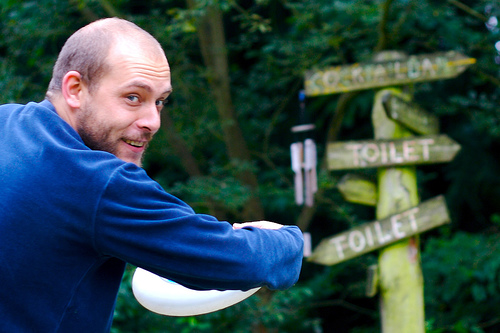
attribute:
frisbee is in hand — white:
[130, 226, 266, 316]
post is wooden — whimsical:
[369, 46, 429, 330]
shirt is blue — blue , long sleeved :
[0, 95, 306, 332]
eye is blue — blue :
[155, 94, 168, 108]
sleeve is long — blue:
[89, 162, 309, 299]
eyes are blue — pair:
[122, 90, 166, 110]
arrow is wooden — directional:
[380, 92, 444, 139]